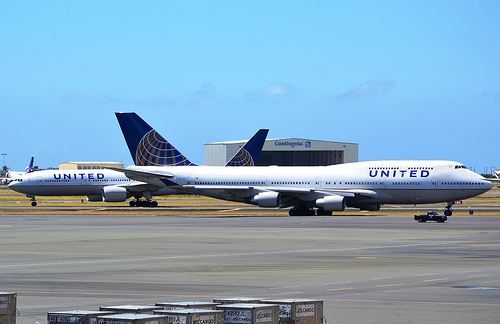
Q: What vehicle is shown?
A: Airplane.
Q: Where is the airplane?
A: Airport.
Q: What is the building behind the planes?
A: Hangar.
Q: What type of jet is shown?
A: Passenger.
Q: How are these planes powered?
A: Jet engine.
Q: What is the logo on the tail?
A: Globe.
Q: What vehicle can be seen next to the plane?
A: Truck.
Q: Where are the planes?
A: Airport.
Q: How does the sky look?
A: Clear and blue.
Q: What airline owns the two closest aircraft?
A: United Airlines owns them.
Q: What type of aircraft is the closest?
A: A Boeing 747.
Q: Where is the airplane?
A: Airport parking lot.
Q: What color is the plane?
A: White.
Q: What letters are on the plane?
A: United.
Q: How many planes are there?
A: Two.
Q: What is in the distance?
A: Building.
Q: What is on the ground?
A: Boxes.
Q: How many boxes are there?
A: Eight.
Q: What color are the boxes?
A: Brown.